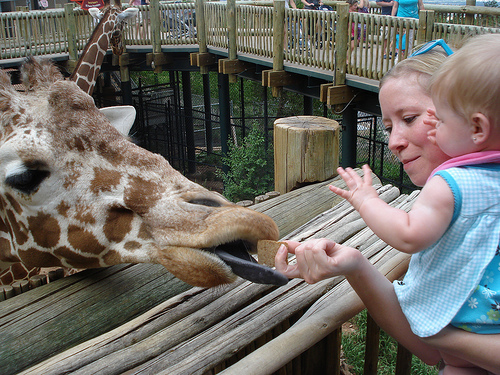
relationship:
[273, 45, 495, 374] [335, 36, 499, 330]
woman holding baby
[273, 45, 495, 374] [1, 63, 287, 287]
woman feeds giraffe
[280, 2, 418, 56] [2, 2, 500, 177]
people in background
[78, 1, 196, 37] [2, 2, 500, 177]
people in background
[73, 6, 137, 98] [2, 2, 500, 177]
giraffe in background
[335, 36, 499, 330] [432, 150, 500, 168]
baby wears bib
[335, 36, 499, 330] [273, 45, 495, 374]
baby touches mom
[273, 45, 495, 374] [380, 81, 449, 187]
mom has face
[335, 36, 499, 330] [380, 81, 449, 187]
baby touches face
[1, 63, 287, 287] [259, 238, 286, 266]
giraffe has treat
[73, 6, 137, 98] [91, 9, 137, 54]
giraffe has head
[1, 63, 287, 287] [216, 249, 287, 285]
giraffe has tongue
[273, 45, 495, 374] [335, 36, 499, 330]
woman holds baby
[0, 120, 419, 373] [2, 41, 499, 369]
fence between giraffe and people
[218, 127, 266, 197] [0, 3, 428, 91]
tree under fence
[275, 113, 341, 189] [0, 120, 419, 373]
post on fence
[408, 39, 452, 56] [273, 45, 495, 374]
sunglasses on woman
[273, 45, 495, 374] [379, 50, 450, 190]
woman has head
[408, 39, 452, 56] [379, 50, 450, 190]
sunglasses on head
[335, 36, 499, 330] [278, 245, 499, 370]
baby in arms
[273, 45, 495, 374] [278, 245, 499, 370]
woman has arms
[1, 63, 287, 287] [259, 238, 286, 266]
giraffe has cracker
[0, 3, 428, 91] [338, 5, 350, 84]
fence has post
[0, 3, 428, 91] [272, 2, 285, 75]
fence has post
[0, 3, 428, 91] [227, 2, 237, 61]
fence has post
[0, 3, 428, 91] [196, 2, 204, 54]
fence has post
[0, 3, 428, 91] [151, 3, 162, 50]
fence has post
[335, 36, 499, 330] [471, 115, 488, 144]
baby has ear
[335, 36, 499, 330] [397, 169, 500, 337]
baby has dress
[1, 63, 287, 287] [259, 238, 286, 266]
giraffe eats treat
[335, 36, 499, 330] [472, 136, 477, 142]
baby wears earring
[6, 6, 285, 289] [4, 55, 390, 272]
giraffes in enclosure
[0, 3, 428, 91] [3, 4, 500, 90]
fence on boardwalk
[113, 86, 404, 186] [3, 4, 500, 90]
fence under boardwalk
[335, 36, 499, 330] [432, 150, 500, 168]
baby wearing bib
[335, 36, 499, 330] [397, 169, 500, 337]
baby wearing dress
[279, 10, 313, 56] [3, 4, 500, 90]
stroller on boardwalk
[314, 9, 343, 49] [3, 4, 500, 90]
stroller on boardwalk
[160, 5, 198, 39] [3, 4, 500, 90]
stroller on boardwalk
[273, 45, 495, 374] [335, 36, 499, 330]
woman carries baby